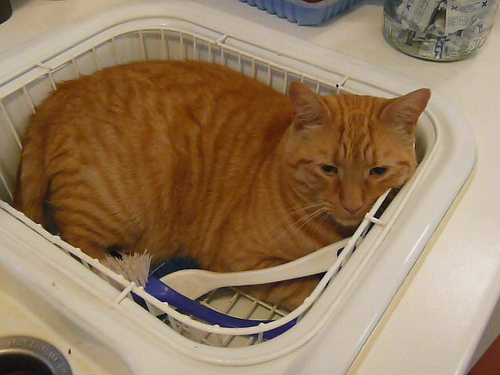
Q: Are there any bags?
A: No, there are no bags.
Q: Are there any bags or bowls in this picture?
A: No, there are no bags or bowls.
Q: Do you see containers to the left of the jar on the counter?
A: Yes, there is a container to the left of the jar.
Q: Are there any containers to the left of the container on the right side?
A: Yes, there is a container to the left of the jar.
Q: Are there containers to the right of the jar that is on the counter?
A: No, the container is to the left of the jar.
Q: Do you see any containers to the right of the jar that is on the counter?
A: No, the container is to the left of the jar.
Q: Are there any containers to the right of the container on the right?
A: No, the container is to the left of the jar.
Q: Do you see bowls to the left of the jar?
A: No, there is a container to the left of the jar.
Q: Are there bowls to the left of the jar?
A: No, there is a container to the left of the jar.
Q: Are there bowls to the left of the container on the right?
A: No, there is a container to the left of the jar.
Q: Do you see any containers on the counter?
A: Yes, there is a container on the counter.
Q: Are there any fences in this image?
A: No, there are no fences.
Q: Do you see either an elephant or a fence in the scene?
A: No, there are no fences or elephants.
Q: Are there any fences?
A: No, there are no fences.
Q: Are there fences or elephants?
A: No, there are no fences or elephants.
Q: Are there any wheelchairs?
A: No, there are no wheelchairs.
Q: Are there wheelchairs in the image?
A: No, there are no wheelchairs.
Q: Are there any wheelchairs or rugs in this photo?
A: No, there are no wheelchairs or rugs.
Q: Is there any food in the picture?
A: No, there is no food.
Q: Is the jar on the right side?
A: Yes, the jar is on the right of the image.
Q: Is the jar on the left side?
A: No, the jar is on the right of the image.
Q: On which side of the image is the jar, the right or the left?
A: The jar is on the right of the image.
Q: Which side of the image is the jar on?
A: The jar is on the right of the image.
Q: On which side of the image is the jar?
A: The jar is on the right of the image.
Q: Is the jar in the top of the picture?
A: Yes, the jar is in the top of the image.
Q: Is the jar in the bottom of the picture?
A: No, the jar is in the top of the image.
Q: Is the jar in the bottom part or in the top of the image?
A: The jar is in the top of the image.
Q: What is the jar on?
A: The jar is on the counter.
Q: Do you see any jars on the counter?
A: Yes, there is a jar on the counter.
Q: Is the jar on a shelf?
A: No, the jar is on the counter.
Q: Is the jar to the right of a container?
A: Yes, the jar is to the right of a container.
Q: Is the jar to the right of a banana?
A: No, the jar is to the right of a container.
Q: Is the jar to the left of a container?
A: No, the jar is to the right of a container.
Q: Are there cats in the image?
A: Yes, there is a cat.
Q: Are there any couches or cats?
A: Yes, there is a cat.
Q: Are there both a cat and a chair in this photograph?
A: No, there is a cat but no chairs.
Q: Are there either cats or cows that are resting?
A: Yes, the cat is resting.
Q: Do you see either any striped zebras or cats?
A: Yes, there is a striped cat.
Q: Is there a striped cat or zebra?
A: Yes, there is a striped cat.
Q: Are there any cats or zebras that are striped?
A: Yes, the cat is striped.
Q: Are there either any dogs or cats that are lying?
A: Yes, the cat is lying.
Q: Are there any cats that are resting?
A: Yes, there is a cat that is resting.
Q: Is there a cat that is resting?
A: Yes, there is a cat that is resting.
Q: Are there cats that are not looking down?
A: Yes, there is a cat that is resting.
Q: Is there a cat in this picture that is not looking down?
A: Yes, there is a cat that is resting.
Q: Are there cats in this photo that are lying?
A: Yes, there is a cat that is lying.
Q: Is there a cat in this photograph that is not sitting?
A: Yes, there is a cat that is lying.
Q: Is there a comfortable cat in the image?
A: Yes, there is a comfortable cat.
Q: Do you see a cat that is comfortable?
A: Yes, there is a comfortable cat.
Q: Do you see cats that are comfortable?
A: Yes, there is a cat that is comfortable.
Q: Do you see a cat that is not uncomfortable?
A: Yes, there is an comfortable cat.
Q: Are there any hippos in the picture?
A: No, there are no hippos.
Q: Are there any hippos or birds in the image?
A: No, there are no hippos or birds.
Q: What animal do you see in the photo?
A: The animal is a cat.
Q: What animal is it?
A: The animal is a cat.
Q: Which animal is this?
A: This is a cat.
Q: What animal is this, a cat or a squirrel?
A: This is a cat.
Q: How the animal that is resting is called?
A: The animal is a cat.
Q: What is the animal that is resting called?
A: The animal is a cat.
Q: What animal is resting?
A: The animal is a cat.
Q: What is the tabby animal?
A: The animal is a cat.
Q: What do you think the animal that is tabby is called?
A: The animal is a cat.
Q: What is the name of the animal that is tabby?
A: The animal is a cat.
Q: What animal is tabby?
A: The animal is a cat.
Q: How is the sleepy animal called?
A: The animal is a cat.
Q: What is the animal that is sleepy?
A: The animal is a cat.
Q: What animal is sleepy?
A: The animal is a cat.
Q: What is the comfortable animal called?
A: The animal is a cat.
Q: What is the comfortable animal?
A: The animal is a cat.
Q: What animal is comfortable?
A: The animal is a cat.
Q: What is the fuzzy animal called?
A: The animal is a cat.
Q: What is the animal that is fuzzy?
A: The animal is a cat.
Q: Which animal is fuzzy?
A: The animal is a cat.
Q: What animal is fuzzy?
A: The animal is a cat.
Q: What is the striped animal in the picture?
A: The animal is a cat.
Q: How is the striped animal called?
A: The animal is a cat.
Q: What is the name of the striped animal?
A: The animal is a cat.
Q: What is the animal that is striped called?
A: The animal is a cat.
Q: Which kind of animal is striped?
A: The animal is a cat.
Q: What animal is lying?
A: The animal is a cat.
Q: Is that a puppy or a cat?
A: That is a cat.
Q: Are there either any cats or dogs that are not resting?
A: No, there is a cat but it is resting.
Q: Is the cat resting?
A: Yes, the cat is resting.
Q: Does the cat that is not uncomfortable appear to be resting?
A: Yes, the cat is resting.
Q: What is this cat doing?
A: The cat is resting.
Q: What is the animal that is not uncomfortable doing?
A: The cat is resting.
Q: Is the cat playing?
A: No, the cat is resting.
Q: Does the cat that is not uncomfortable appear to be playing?
A: No, the cat is resting.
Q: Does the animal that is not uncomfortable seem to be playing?
A: No, the cat is resting.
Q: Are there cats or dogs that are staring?
A: No, there is a cat but it is resting.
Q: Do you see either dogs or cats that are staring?
A: No, there is a cat but it is resting.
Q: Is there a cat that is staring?
A: No, there is a cat but it is resting.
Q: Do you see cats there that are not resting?
A: No, there is a cat but it is resting.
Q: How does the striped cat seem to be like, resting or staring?
A: The cat is resting.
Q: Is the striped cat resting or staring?
A: The cat is resting.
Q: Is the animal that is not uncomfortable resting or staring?
A: The cat is resting.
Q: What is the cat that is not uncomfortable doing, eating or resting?
A: The cat is resting.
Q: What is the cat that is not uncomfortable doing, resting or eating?
A: The cat is resting.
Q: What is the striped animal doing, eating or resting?
A: The cat is resting.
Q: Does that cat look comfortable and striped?
A: Yes, the cat is comfortable and striped.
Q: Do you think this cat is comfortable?
A: Yes, the cat is comfortable.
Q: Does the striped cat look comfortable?
A: Yes, the cat is comfortable.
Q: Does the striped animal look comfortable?
A: Yes, the cat is comfortable.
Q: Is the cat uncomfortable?
A: No, the cat is comfortable.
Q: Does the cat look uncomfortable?
A: No, the cat is comfortable.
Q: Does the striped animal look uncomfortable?
A: No, the cat is comfortable.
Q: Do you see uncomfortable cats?
A: No, there is a cat but it is comfortable.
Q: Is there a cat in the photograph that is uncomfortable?
A: No, there is a cat but it is comfortable.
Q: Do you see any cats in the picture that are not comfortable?
A: No, there is a cat but it is comfortable.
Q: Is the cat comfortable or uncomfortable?
A: The cat is comfortable.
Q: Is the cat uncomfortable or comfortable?
A: The cat is comfortable.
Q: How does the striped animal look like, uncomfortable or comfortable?
A: The cat is comfortable.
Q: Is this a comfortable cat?
A: Yes, this is a comfortable cat.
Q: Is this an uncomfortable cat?
A: No, this is a comfortable cat.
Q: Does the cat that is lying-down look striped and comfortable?
A: Yes, the cat is striped and comfortable.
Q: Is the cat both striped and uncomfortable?
A: No, the cat is striped but comfortable.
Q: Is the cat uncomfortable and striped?
A: No, the cat is striped but comfortable.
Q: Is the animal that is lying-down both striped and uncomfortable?
A: No, the cat is striped but comfortable.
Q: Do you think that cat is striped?
A: Yes, the cat is striped.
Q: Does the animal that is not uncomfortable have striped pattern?
A: Yes, the cat is striped.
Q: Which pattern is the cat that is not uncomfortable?
A: The cat is striped.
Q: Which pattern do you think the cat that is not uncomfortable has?
A: The cat has striped pattern.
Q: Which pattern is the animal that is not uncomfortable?
A: The cat is striped.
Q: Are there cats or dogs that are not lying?
A: No, there is a cat but it is lying.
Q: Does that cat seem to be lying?
A: Yes, the cat is lying.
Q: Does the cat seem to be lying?
A: Yes, the cat is lying.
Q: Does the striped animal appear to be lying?
A: Yes, the cat is lying.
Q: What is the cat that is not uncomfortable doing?
A: The cat is lying.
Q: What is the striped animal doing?
A: The cat is lying.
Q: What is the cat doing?
A: The cat is lying.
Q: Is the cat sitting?
A: No, the cat is lying.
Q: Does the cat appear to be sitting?
A: No, the cat is lying.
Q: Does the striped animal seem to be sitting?
A: No, the cat is lying.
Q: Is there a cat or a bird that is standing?
A: No, there is a cat but it is lying.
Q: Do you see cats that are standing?
A: No, there is a cat but it is lying.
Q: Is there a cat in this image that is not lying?
A: No, there is a cat but it is lying.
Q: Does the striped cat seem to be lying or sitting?
A: The cat is lying.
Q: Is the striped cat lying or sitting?
A: The cat is lying.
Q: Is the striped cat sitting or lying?
A: The cat is lying.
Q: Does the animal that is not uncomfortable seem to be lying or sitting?
A: The cat is lying.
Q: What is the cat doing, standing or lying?
A: The cat is lying.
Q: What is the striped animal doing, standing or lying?
A: The cat is lying.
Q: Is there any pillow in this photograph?
A: No, there are no pillows.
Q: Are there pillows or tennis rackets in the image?
A: No, there are no pillows or tennis rackets.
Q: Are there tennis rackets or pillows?
A: No, there are no pillows or tennis rackets.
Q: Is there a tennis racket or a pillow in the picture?
A: No, there are no pillows or rackets.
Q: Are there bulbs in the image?
A: No, there are no bulbs.